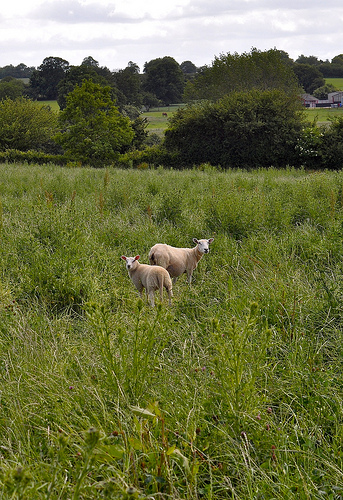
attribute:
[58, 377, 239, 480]
green grass — tall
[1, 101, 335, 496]
grass — brown, green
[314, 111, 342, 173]
tree — green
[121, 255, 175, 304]
sheep — brown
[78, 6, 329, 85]
clouds — white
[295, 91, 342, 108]
house — gray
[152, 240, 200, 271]
sheep — light , brown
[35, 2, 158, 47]
clouds — white